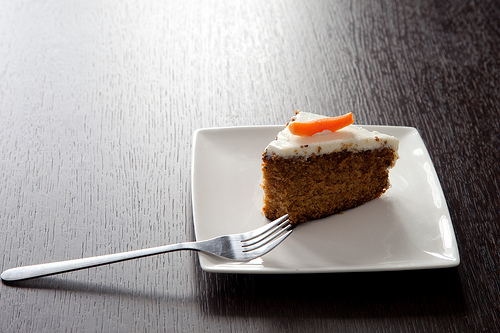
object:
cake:
[261, 109, 400, 231]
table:
[0, 0, 499, 333]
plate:
[191, 123, 461, 268]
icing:
[263, 111, 399, 155]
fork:
[0, 214, 292, 282]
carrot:
[289, 112, 354, 136]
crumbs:
[265, 137, 398, 156]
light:
[224, 238, 262, 255]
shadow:
[29, 277, 200, 307]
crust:
[264, 194, 391, 230]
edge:
[0, 271, 7, 281]